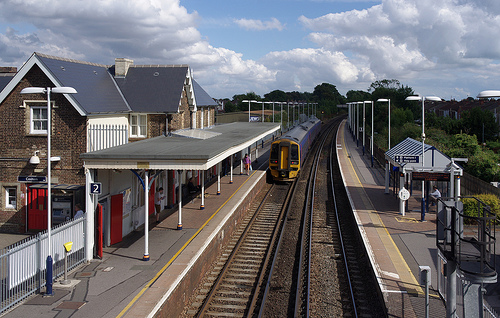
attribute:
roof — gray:
[37, 54, 128, 119]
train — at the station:
[268, 115, 324, 182]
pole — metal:
[195, 174, 210, 211]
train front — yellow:
[274, 137, 304, 189]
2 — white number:
[89, 181, 106, 195]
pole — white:
[126, 161, 174, 248]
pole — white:
[227, 149, 237, 187]